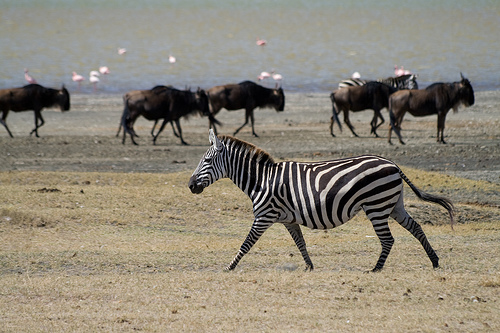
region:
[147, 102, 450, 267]
zebra on the ground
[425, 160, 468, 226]
tail of the zebra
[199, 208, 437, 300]
legs of the zebra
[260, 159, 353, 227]
black and white body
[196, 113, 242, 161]
ears of the zebra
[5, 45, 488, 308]
many animals in the photo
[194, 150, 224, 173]
eye of the zebra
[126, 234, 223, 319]
ground under the zebra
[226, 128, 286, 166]
hair on back of zebra's neck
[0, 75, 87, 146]
brown animal in photo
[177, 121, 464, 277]
a zebra walking on a savana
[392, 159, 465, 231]
the tail of a zebra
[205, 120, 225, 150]
the ear of a zebra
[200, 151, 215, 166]
the eye of a zebra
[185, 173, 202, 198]
the nose of a zebra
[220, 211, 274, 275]
the front leg of a zebra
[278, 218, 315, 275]
the front leg of a zebra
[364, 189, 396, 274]
the hind leg of a zebra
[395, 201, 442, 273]
the hind leg of a zebra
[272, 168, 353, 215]
the stripes on the coat of a zebra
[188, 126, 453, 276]
Zebra on a field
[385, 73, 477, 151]
Wilderbeast on the field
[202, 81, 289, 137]
Wilderbeast on the field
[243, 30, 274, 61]
Bird in the background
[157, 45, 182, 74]
Bird in the background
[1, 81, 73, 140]
Wilderbeast in the background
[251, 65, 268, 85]
Bird in the background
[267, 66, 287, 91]
Bird in the background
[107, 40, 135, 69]
Bird in the background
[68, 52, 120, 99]
Birds in the background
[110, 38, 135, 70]
flamingos in the background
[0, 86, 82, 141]
elk walking in the background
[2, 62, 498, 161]
a group of elk walking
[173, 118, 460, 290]
zebra walking on ground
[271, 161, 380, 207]
stripes on a zebra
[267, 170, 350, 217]
black and white stripes on zebra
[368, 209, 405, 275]
legs of a zebra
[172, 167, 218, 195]
mouth of a zebra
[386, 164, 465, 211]
tail of a zebra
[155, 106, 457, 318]
the zebra is walking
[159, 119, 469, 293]
the zebra is walking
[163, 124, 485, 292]
the zebra is walking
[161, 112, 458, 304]
the zebra is walking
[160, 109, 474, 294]
the zebra is walking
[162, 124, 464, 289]
black and white stripes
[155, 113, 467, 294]
black and white stripes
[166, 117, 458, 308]
black and white stripes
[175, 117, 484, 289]
black and white stripes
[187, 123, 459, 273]
The zebra in the field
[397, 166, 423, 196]
The tail of the zebra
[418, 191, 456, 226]
The hair on the tail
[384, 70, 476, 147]
The wildabeast on the beach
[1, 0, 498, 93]
The water beyond the beach